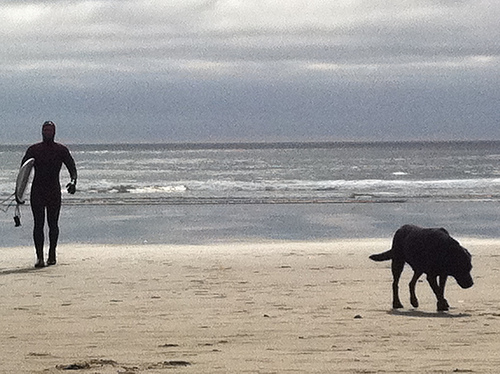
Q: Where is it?
A: This is at the beach.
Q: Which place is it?
A: It is a beach.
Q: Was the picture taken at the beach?
A: Yes, it was taken in the beach.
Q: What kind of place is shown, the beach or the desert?
A: It is the beach.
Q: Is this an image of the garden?
A: No, the picture is showing the beach.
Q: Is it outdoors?
A: Yes, it is outdoors.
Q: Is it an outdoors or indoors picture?
A: It is outdoors.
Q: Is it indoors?
A: No, it is outdoors.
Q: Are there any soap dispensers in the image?
A: No, there are no soap dispensers.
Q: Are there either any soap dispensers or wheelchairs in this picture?
A: No, there are no soap dispensers or wheelchairs.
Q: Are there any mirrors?
A: No, there are no mirrors.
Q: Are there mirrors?
A: No, there are no mirrors.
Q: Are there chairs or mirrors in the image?
A: No, there are no mirrors or chairs.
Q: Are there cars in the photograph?
A: No, there are no cars.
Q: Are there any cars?
A: No, there are no cars.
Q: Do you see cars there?
A: No, there are no cars.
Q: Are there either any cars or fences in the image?
A: No, there are no cars or fences.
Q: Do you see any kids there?
A: No, there are no kids.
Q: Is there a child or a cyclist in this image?
A: No, there are no children or cyclists.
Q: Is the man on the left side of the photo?
A: Yes, the man is on the left of the image.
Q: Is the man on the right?
A: No, the man is on the left of the image.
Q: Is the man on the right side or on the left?
A: The man is on the left of the image.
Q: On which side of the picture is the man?
A: The man is on the left of the image.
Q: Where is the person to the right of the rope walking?
A: The man is walking on the beach.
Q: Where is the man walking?
A: The man is walking on the beach.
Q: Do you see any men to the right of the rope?
A: Yes, there is a man to the right of the rope.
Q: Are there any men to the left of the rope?
A: No, the man is to the right of the rope.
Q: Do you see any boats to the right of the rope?
A: No, there is a man to the right of the rope.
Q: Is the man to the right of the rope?
A: Yes, the man is to the right of the rope.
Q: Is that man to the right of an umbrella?
A: No, the man is to the right of the rope.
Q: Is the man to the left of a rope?
A: No, the man is to the right of a rope.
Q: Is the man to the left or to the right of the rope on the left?
A: The man is to the right of the rope.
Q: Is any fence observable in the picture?
A: No, there are no fences.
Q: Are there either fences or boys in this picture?
A: No, there are no fences or boys.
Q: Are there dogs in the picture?
A: Yes, there is a dog.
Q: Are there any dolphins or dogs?
A: Yes, there is a dog.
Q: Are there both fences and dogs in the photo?
A: No, there is a dog but no fences.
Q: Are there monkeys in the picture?
A: No, there are no monkeys.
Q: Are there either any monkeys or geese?
A: No, there are no monkeys or geese.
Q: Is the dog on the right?
A: Yes, the dog is on the right of the image.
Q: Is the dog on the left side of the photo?
A: No, the dog is on the right of the image.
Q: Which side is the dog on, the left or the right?
A: The dog is on the right of the image.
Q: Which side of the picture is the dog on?
A: The dog is on the right of the image.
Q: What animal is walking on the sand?
A: The dog is walking on the sand.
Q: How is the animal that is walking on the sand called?
A: The animal is a dog.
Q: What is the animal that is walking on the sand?
A: The animal is a dog.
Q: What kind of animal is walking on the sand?
A: The animal is a dog.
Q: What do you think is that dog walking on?
A: The dog is walking on the sand.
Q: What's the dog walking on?
A: The dog is walking on the sand.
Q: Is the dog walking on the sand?
A: Yes, the dog is walking on the sand.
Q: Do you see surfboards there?
A: Yes, there is a surfboard.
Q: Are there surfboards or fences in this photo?
A: Yes, there is a surfboard.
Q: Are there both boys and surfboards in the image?
A: No, there is a surfboard but no boys.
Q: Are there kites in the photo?
A: No, there are no kites.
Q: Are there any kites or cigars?
A: No, there are no kites or cigars.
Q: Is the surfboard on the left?
A: Yes, the surfboard is on the left of the image.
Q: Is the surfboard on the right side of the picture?
A: No, the surfboard is on the left of the image.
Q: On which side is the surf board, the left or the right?
A: The surf board is on the left of the image.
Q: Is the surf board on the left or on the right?
A: The surf board is on the left of the image.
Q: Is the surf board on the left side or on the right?
A: The surf board is on the left of the image.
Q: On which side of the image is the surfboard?
A: The surfboard is on the left of the image.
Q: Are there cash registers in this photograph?
A: No, there are no cash registers.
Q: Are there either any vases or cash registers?
A: No, there are no cash registers or vases.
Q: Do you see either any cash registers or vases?
A: No, there are no cash registers or vases.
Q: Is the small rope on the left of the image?
A: Yes, the rope is on the left of the image.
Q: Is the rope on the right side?
A: No, the rope is on the left of the image.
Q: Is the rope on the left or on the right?
A: The rope is on the left of the image.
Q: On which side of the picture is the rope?
A: The rope is on the left of the image.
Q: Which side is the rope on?
A: The rope is on the left of the image.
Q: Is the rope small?
A: Yes, the rope is small.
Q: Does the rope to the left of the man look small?
A: Yes, the rope is small.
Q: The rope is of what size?
A: The rope is small.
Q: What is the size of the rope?
A: The rope is small.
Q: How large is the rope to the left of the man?
A: The rope is small.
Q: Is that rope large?
A: No, the rope is small.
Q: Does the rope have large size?
A: No, the rope is small.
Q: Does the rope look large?
A: No, the rope is small.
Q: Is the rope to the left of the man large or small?
A: The rope is small.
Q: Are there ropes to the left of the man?
A: Yes, there is a rope to the left of the man.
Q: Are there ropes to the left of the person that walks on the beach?
A: Yes, there is a rope to the left of the man.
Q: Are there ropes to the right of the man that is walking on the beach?
A: No, the rope is to the left of the man.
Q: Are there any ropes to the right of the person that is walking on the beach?
A: No, the rope is to the left of the man.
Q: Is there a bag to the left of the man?
A: No, there is a rope to the left of the man.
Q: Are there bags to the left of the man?
A: No, there is a rope to the left of the man.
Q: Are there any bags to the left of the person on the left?
A: No, there is a rope to the left of the man.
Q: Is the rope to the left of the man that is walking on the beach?
A: Yes, the rope is to the left of the man.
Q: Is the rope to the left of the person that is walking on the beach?
A: Yes, the rope is to the left of the man.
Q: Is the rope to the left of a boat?
A: No, the rope is to the left of the man.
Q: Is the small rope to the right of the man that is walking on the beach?
A: No, the rope is to the left of the man.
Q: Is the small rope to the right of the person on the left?
A: No, the rope is to the left of the man.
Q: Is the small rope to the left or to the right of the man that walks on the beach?
A: The rope is to the left of the man.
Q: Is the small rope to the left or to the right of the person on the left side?
A: The rope is to the left of the man.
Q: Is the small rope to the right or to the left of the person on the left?
A: The rope is to the left of the man.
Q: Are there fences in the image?
A: No, there are no fences.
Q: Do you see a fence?
A: No, there are no fences.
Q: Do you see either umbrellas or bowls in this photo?
A: No, there are no umbrellas or bowls.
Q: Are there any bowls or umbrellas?
A: No, there are no umbrellas or bowls.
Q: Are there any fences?
A: No, there are no fences.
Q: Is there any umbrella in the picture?
A: No, there are no umbrellas.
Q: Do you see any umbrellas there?
A: No, there are no umbrellas.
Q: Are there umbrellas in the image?
A: No, there are no umbrellas.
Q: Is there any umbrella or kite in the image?
A: No, there are no umbrellas or kites.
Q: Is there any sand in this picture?
A: Yes, there is sand.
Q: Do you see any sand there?
A: Yes, there is sand.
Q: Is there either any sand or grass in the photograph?
A: Yes, there is sand.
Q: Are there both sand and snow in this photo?
A: No, there is sand but no snow.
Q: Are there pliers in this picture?
A: No, there are no pliers.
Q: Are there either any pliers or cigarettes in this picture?
A: No, there are no pliers or cigarettes.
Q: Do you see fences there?
A: No, there are no fences.